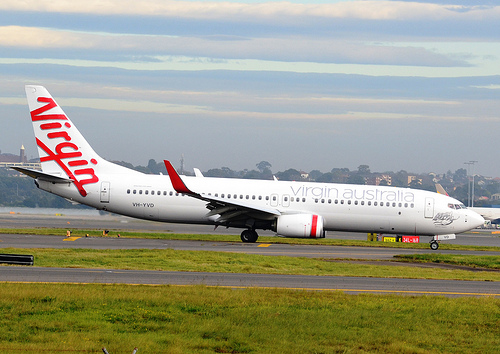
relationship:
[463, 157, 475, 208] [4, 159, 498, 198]
poles on background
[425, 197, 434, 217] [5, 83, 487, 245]
door on airplane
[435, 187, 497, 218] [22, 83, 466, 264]
windshields on jet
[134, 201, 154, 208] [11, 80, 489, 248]
code on airplane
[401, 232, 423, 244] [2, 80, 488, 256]
sign at airport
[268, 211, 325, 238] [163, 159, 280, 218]
engine under airplane wing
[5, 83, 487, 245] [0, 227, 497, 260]
airplane on runway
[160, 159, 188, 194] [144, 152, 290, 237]
upturned tip of airplane wing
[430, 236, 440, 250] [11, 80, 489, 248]
wheel on airplane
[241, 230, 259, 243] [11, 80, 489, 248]
wheel on airplane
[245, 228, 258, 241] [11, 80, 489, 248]
wheel on airplane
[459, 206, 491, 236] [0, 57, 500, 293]
nose of airplane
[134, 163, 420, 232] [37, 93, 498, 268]
windows on side of airplane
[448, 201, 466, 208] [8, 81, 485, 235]
windows on cockpit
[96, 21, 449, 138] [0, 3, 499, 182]
clouds in sky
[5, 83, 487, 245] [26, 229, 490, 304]
airplane stopped on runway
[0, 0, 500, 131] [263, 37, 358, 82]
clouds in sky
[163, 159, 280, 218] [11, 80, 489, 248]
airplane wing on airplane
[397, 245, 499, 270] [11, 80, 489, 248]
grass in front of airplane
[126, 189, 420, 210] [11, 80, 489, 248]
windows on airplane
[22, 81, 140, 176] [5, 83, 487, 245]
tail wing on airplane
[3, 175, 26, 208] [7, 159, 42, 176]
trees and building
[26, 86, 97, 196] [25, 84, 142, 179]
logo on tail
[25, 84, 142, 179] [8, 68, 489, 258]
tail of jet plane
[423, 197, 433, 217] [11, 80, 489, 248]
door of airplane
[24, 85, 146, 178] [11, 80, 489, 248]
tail wing of airplane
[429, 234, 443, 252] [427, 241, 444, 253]
landing gear of plane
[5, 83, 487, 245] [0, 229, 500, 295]
airplane on runway